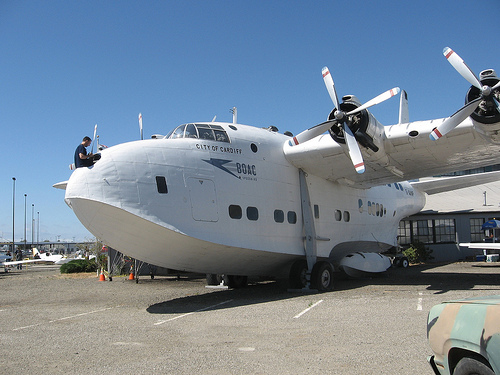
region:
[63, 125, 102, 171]
a man working on the plane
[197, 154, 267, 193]
a label on the side of the plane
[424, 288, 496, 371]
a camouflage vehicle on the side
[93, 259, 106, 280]
a traffic cone behind the plane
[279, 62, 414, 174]
a propeller on the left wing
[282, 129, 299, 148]
a red and blue line on the propeller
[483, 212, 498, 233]
an umbrella in front of the building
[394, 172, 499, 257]
a building behind the plane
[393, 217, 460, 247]
windows on the building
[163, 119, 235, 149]
a cockpit window on the front of the plane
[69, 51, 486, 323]
white airplane on ground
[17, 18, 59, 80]
white clouds in blue sky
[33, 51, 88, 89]
white clouds in blue sky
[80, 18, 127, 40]
white clouds in blue sky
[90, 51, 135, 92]
white clouds in blue sky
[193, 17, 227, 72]
white clouds in blue sky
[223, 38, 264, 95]
white clouds in blue sky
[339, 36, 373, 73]
white clouds in blue sky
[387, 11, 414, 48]
white clouds in blue sky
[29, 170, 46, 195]
white clouds in blue sky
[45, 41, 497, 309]
a plane in an airport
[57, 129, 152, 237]
a man on the nose of plane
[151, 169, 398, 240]
windows on side of plane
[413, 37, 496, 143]
a propeller on right wing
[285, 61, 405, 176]
a propeller on right wing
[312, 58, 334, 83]
tip of blade has a red stripe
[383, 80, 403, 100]
tip of blade has a red stripe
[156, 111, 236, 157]
windows in the cockpit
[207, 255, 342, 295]
front wheels of plane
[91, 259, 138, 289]
cones are color orange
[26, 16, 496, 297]
a large airplane parked in a parking lot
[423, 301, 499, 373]
The end of a camoflauge painted vehicle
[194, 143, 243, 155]
City of Cardiff painted on the side of the plane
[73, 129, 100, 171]
a man working on the nose of the airplane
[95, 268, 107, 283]
a flourescent orange traffic cone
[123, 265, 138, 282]
a flourescent orange traffic cone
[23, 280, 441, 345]
the white markings indicating parking spots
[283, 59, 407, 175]
a large, red and white plane propellor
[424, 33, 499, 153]
a large, red and white plane propellor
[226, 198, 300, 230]
windows of the large white airplane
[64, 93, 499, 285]
white airplane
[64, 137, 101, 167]
person sitting on nose of airplane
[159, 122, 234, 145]
cockpit of white airplane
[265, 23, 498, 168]
two propellors on white airplane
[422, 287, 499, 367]
truck painted camoflauge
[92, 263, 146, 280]
two orange safety cones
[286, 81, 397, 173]
plane propellor with four blades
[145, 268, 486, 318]
plane's shadow on the pavement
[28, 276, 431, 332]
white lines painted on pavement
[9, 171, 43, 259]
four street lights